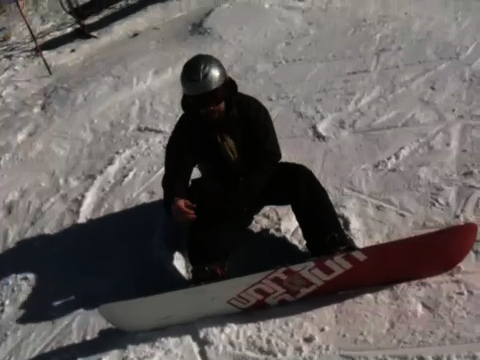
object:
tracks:
[0, 0, 480, 360]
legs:
[174, 161, 355, 270]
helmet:
[180, 54, 228, 96]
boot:
[305, 237, 359, 257]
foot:
[189, 262, 235, 287]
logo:
[227, 251, 367, 311]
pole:
[13, 0, 52, 77]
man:
[162, 54, 359, 287]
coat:
[160, 91, 281, 203]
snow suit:
[96, 54, 477, 332]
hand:
[171, 199, 196, 225]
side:
[98, 221, 478, 334]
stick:
[14, 0, 54, 75]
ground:
[0, 0, 479, 360]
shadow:
[32, 0, 164, 52]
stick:
[58, 1, 88, 25]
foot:
[306, 240, 362, 259]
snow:
[0, 0, 480, 359]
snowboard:
[97, 222, 477, 334]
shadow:
[0, 198, 193, 360]